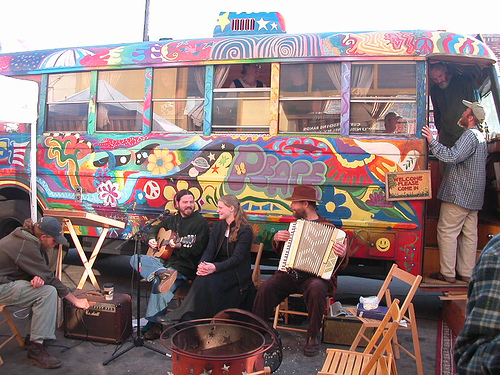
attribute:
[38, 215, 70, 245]
hat — grey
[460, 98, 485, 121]
hat — grey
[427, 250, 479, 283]
boot — brown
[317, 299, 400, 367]
chair — wooden, empty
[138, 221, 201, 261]
guitar — accustic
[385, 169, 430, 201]
sign — welcome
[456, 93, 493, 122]
hat — brown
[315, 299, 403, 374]
folding chair — wooden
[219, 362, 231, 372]
star — hole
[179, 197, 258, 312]
woman — young, blonde, smiling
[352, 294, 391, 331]
book — blue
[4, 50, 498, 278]
bus — gypsy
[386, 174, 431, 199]
sign — welcome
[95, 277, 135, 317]
cup — coffee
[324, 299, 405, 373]
folding chair — small, wooden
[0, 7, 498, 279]
bus — large, painted, bright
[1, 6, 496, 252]
bus — large, colorful, hippy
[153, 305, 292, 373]
fire pit — small, red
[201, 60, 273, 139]
window — open